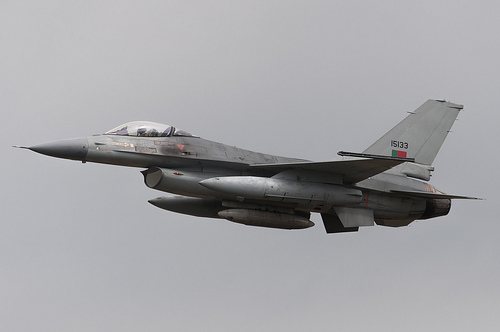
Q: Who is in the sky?
A: Jet fighter.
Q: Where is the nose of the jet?
A: In the front.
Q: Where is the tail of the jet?
A: In back.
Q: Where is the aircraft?
A: In the sky.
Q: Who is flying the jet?
A: Pilot.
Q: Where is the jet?
A: In the sky.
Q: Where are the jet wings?
A: On the sides.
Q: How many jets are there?
A: One.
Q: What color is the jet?
A: Gray.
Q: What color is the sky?
A: Gray.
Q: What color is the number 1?
A: Black.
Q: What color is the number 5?
A: Black.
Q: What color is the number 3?
A: Black.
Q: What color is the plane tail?
A: Gray.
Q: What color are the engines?
A: Gray.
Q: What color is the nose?
A: Gray.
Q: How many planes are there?
A: One.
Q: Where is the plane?
A: In the sky.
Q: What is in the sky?
A: A plane.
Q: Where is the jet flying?
A: In the sky.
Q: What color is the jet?
A: Silver.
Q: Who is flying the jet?
A: A person.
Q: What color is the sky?
A: Grey.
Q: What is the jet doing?
A: Flying.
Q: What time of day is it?
A: Day time.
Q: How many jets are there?
A: One.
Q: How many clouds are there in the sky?
A: Zero.